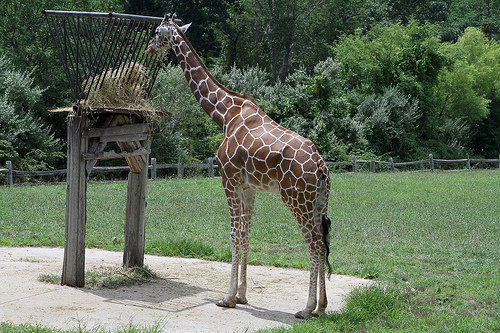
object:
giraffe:
[156, 14, 335, 320]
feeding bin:
[49, 5, 167, 111]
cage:
[50, 9, 166, 109]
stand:
[60, 111, 150, 298]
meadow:
[0, 168, 499, 333]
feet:
[214, 291, 243, 309]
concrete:
[0, 244, 370, 333]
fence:
[0, 157, 500, 185]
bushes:
[229, 73, 401, 151]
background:
[7, 17, 482, 161]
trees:
[202, 0, 392, 109]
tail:
[321, 178, 335, 281]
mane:
[178, 30, 265, 123]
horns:
[162, 10, 178, 24]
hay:
[83, 64, 144, 104]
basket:
[44, 11, 183, 105]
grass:
[0, 169, 500, 333]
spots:
[226, 133, 287, 165]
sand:
[0, 245, 376, 333]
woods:
[140, 16, 483, 140]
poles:
[59, 108, 90, 288]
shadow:
[233, 296, 309, 325]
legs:
[291, 201, 329, 320]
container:
[51, 11, 175, 120]